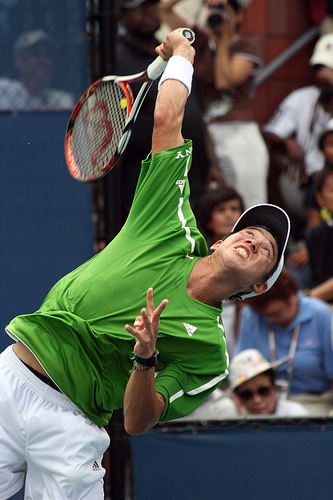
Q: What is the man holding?
A: Tennis racket.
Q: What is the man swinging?
A: Tennis racket.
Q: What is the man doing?
A: Playing tennis.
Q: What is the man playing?
A: Tennis.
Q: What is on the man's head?
A: On the hat.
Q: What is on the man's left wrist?
A: Wrist band.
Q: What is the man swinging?
A: Tennis racket.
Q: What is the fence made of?
A: Metal.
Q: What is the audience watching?
A: Tennis match.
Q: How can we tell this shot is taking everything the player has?
A: The expression shows extreme stress and agitation.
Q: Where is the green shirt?
A: On a player, flinging his arm back, to meet the ball.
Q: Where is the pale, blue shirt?
A: On a woman with a lanyard,moving behind a person with glasses,in the stands.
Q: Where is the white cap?
A: On the head of the player.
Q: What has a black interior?
A: A white cap.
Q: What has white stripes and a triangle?
A: The player's shirt.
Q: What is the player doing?
A: Playing tennis.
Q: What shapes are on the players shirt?
A: Triangles.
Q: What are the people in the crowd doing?
A: Watching the game.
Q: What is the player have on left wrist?
A: Sweat band.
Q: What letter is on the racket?
A: B.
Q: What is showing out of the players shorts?
A: Underware.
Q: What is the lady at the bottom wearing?
A: Hat.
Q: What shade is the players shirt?
A: Green.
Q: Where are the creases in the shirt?
A: Bottom of the shirt.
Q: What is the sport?
A: Tennis.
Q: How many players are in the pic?
A: One.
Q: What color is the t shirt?
A: Green.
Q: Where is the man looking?
A: Up.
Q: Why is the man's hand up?
A: To hit the ball.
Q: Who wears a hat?
A: A woman.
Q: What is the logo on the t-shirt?
A: Adidas.